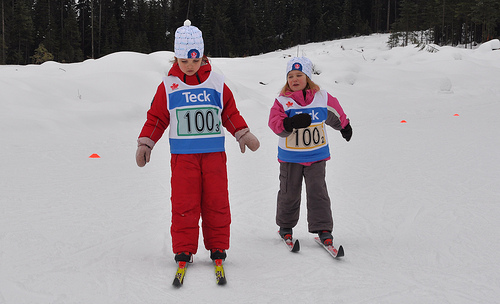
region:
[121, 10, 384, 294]
two young children skiing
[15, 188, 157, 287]
white snow on the ground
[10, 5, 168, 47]
green trees in the background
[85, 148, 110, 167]
orange safety cones in the snow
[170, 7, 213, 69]
white hat on a child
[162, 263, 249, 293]
front of skis of a child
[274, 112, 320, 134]
black mitten of little girl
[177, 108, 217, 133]
Number 100 on front of vest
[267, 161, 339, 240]
grey ski pants of little girl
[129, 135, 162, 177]
beige mitten on a child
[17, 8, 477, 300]
a winter landscape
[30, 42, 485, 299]
snow is on the ground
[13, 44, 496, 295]
the snow is white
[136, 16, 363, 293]
two girls are skiing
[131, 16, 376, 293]
the two girls are on skis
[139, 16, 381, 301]
the two girls do not hold ski poles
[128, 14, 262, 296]
the girl on the left is wearing a red ski suit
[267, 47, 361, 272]
the girl on the right is wearing a pink coat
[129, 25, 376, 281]
both girls have white hats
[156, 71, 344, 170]
both girls wear a white vest with a number on it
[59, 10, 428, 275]
2 children learning to ski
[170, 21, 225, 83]
a girl wearing a white knit hat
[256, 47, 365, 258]
a girl in a pink jacket on skis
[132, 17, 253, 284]
a young girl looking at the ground in front of her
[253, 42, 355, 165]
a young girl looking at her sister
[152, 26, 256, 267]
a girl in a red snow suit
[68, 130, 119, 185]
a trail marker in the snow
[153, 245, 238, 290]
a pair of small yellow skiis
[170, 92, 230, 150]
a bib with the number 100 on it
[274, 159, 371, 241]
a pair of brown ski pants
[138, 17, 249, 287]
this is a child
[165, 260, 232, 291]
he is wearing skiis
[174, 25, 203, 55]
she is wearing a marvin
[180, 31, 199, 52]
the marvin is white in color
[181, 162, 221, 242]
the trousers are red in color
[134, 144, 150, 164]
this is a glove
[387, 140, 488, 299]
the place is full of snow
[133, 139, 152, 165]
the glove is warm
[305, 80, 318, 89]
the hair is long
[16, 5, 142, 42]
the trees are long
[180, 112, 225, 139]
number on bib on girl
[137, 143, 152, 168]
brown mitten on hand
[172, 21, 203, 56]
hat on girl's head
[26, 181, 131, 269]
an area of snow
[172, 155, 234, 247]
orange ski pants on girl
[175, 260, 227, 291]
yellow skis on snow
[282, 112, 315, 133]
dark brown mitten on girl's hand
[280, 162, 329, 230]
gray ski pants worn by girl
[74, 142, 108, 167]
an orange object in snow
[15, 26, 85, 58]
trees in background